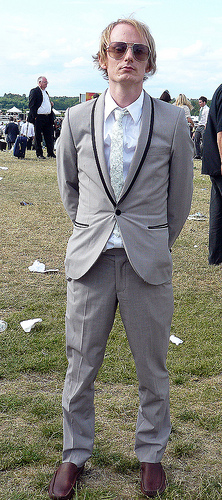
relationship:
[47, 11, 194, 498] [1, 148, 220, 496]
man on grass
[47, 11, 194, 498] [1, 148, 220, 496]
man above grass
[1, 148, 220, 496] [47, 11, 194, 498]
grass under man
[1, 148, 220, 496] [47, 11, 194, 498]
grass below man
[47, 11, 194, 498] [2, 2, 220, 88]
man under sky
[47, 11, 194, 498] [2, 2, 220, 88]
man below sky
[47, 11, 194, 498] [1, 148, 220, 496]
man near grass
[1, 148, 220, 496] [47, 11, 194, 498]
grass near man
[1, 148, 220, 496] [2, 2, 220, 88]
grass under sky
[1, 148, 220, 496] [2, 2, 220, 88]
grass below sky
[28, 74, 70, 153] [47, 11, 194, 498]
man behind man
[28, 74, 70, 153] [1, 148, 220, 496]
man on grass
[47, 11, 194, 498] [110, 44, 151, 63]
man wearing glasses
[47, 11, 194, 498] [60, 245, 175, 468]
man wearing pants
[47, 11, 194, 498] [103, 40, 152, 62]
man wearing sunglasses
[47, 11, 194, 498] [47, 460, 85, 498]
man wearing shoe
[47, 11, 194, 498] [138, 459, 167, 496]
man wearing shoe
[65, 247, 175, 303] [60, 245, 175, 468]
midsection belonging to pants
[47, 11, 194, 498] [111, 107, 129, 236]
man wearing tie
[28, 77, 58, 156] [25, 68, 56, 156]
man in suit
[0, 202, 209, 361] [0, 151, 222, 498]
garbage on ground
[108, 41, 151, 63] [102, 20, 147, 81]
glasses on face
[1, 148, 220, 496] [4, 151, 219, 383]
grass on ground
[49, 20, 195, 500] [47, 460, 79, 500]
man wearing shoe